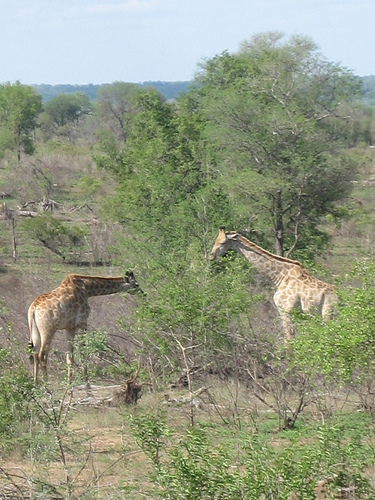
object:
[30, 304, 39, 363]
tail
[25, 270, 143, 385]
giraffe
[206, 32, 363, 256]
tree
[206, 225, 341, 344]
giraffe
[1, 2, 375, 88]
sky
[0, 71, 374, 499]
ground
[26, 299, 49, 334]
rear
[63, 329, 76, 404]
leg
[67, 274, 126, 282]
hair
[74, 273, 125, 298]
neck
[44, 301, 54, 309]
spot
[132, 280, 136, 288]
eye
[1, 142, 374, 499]
grass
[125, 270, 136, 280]
horn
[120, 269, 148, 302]
head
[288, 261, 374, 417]
tree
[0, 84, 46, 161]
tree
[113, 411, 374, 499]
tree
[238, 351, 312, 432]
branches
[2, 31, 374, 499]
savannah